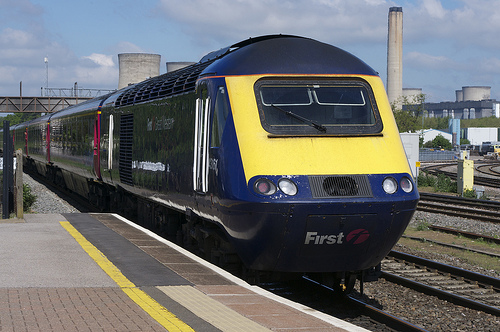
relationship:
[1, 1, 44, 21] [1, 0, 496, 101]
cloud hanging in sky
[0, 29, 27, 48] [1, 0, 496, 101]
cloud hanging in sky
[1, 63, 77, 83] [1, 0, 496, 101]
cloud hanging in sky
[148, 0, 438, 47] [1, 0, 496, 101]
cloud hanging in sky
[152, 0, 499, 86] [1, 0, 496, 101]
cloud hanging in sky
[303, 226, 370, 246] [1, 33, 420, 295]
logo printed on commuter train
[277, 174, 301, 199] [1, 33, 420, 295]
headlight on commuter train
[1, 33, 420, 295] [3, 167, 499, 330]
commuter train on tracks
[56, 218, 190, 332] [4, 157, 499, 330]
line on ground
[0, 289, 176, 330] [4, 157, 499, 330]
brick laid out on ground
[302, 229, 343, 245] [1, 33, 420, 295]
letter on commuter train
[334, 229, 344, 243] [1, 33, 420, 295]
letter on commuter train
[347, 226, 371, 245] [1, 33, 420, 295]
logo on commuter train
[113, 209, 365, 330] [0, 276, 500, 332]
stripe on ground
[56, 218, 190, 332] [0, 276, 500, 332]
line on ground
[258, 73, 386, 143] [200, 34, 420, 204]
windshield on train front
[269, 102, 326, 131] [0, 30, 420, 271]
windshield wiper on train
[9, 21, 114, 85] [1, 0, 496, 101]
white clouds in sky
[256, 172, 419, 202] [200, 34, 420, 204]
headlights on train front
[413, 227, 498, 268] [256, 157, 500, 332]
weeds next to tracks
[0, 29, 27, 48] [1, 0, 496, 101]
cloud in sky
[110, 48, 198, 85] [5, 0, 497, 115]
cooling towers of power plant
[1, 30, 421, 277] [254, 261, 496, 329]
commuter train on tracks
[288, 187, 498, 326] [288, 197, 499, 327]
rails of train tracks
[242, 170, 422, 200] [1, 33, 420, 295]
lights on commuter train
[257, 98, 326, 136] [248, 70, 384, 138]
windshield wiper on windshield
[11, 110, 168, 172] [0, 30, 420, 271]
reflection on side of train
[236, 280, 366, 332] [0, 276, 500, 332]
stripe on edge of ground